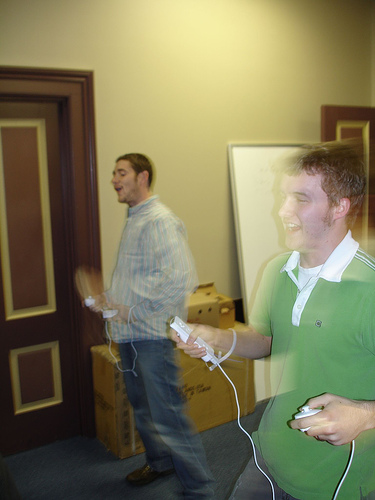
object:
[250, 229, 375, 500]
polo shirt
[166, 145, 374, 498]
man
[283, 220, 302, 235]
smiling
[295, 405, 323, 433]
controller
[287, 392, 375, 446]
hand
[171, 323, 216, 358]
hand.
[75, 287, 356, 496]
wii game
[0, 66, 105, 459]
door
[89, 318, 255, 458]
boxes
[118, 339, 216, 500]
jeans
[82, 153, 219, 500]
man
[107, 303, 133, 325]
hand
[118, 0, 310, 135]
wall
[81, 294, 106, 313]
hand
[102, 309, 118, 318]
controller